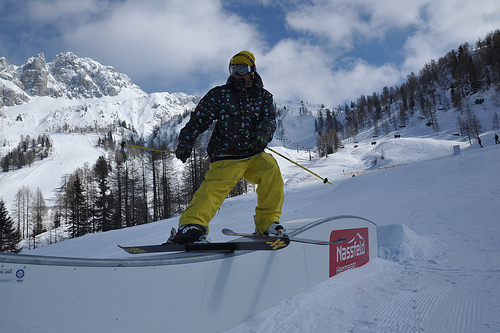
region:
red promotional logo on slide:
[328, 228, 376, 269]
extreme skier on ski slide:
[124, 37, 386, 286]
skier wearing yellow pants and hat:
[151, 46, 298, 266]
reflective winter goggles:
[228, 59, 254, 77]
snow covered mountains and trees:
[4, 46, 174, 221]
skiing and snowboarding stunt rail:
[2, 196, 398, 328]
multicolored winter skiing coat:
[176, 77, 291, 156]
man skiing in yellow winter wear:
[122, 40, 332, 256]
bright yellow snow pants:
[193, 152, 291, 230]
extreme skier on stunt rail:
[0, 42, 385, 332]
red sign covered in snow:
[325, 224, 380, 277]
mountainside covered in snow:
[5, 50, 126, 107]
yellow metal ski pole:
[265, 145, 339, 192]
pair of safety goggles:
[221, 58, 256, 79]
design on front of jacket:
[220, 100, 258, 130]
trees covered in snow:
[372, 54, 475, 137]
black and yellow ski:
[100, 230, 295, 260]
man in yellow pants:
[112, 52, 364, 276]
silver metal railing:
[43, 252, 175, 274]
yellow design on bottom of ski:
[263, 233, 293, 254]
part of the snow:
[437, 199, 449, 207]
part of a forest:
[381, 111, 404, 123]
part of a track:
[195, 190, 207, 217]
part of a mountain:
[59, 100, 70, 118]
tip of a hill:
[82, 71, 101, 106]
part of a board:
[185, 256, 197, 272]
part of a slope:
[78, 102, 106, 143]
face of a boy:
[238, 66, 248, 71]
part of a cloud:
[312, 66, 321, 83]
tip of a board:
[101, 287, 119, 298]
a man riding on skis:
[170, 49, 285, 239]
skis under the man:
[112, 227, 347, 254]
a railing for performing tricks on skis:
[1, 212, 377, 331]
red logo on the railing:
[327, 224, 371, 276]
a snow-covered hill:
[13, 143, 499, 328]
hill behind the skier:
[0, 47, 499, 252]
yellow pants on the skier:
[178, 152, 286, 237]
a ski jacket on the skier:
[178, 81, 276, 157]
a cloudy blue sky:
[0, 0, 498, 96]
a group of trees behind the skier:
[1, 130, 255, 252]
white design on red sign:
[344, 230, 370, 245]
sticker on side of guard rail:
[0, 263, 40, 284]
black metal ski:
[105, 232, 294, 259]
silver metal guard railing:
[5, 245, 118, 269]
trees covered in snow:
[0, 129, 67, 177]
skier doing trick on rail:
[148, 23, 348, 290]